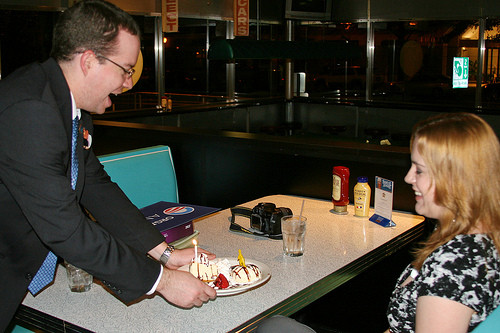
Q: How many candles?
A: Two.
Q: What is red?
A: Ketchup.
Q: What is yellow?
A: Mustard.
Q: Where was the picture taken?
A: Restaurant.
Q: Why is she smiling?
A: Happy.